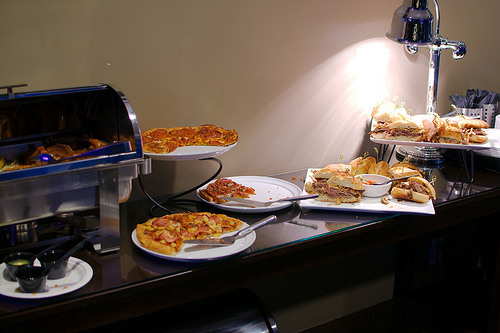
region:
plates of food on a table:
[44, 41, 499, 320]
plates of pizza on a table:
[77, 79, 293, 279]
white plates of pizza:
[117, 87, 307, 315]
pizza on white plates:
[146, 54, 313, 275]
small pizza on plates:
[126, 61, 258, 311]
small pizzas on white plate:
[141, 58, 275, 293]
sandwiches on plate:
[324, 83, 493, 215]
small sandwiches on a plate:
[260, 45, 492, 246]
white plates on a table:
[122, 51, 459, 259]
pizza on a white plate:
[131, 212, 263, 262]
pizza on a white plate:
[138, 124, 234, 158]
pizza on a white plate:
[197, 170, 301, 211]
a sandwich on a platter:
[317, 170, 358, 204]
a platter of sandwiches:
[366, 100, 491, 147]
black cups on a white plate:
[2, 240, 94, 302]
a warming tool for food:
[0, 78, 143, 214]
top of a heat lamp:
[382, 2, 447, 53]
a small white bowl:
[354, 173, 394, 196]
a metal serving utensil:
[183, 213, 279, 245]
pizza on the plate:
[128, 214, 234, 246]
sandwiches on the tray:
[314, 161, 431, 225]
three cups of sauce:
[11, 249, 76, 291]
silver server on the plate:
[173, 219, 278, 250]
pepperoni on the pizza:
[159, 211, 176, 251]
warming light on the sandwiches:
[392, 4, 458, 107]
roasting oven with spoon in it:
[0, 92, 97, 184]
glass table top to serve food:
[254, 207, 363, 247]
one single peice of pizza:
[207, 179, 250, 204]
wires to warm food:
[131, 159, 203, 215]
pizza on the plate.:
[141, 122, 245, 158]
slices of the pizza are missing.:
[140, 124, 240, 164]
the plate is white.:
[190, 167, 310, 214]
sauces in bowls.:
[5, 241, 75, 290]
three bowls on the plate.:
[0, 245, 75, 292]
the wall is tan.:
[0, 3, 486, 174]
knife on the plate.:
[185, 210, 278, 247]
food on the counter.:
[129, 104, 496, 264]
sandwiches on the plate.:
[297, 153, 436, 214]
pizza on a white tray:
[131, 206, 256, 269]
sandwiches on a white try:
[309, 157, 436, 215]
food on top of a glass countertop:
[1, 67, 498, 324]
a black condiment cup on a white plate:
[38, 244, 77, 284]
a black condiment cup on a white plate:
[9, 262, 49, 299]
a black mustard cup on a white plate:
[2, 249, 35, 284]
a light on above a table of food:
[384, 1, 469, 146]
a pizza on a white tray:
[139, 120, 251, 162]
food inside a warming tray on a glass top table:
[2, 136, 130, 173]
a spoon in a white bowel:
[365, 173, 422, 190]